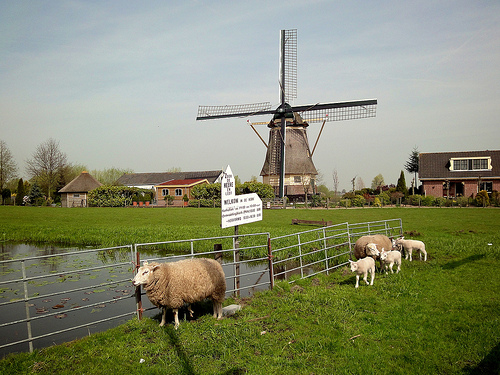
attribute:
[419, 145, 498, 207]
house — has roof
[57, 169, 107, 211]
shack — small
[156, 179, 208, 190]
roof — red, brick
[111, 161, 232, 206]
house — white, large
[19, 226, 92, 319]
pond — small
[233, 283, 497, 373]
grass — green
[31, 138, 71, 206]
tree — bare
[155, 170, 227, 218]
stone house — small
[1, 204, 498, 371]
grass — green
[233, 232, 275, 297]
guard rails — metal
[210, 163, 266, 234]
sign — black, white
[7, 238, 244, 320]
water — with leaves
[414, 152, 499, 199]
house — stone, small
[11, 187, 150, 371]
pond — next to gate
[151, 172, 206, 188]
roof — on a building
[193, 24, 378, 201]
windmill — black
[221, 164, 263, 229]
sign — white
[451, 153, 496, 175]
window — white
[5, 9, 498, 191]
sky — hazy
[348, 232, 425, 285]
group — small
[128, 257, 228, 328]
sheep — adult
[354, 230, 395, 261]
sheep — adult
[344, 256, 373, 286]
sheep — young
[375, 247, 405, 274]
sheep — young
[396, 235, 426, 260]
sheep — young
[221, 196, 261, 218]
lettering — black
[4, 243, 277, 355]
water — still